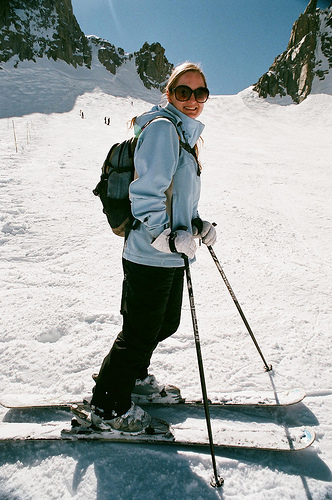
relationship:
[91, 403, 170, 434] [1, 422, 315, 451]
foot standing on ski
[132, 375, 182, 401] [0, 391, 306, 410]
foot standing on ski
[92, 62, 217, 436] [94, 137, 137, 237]
woman wearing backpack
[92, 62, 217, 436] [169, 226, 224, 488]
woman holding ski pole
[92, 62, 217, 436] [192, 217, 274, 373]
woman holding ski pole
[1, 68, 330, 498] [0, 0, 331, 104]
snow resting on mountains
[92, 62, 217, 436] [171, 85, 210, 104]
woman wearing shades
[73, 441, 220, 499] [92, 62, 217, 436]
shadow of woman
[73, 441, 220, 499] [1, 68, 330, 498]
shadow visible on snow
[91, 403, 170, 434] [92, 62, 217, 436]
foot of woman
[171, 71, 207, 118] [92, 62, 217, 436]
face of woman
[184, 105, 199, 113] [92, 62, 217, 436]
mouth of woman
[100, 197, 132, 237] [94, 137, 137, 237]
part of backpack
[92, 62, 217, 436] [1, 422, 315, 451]
woman standing on ski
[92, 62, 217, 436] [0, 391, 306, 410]
woman standing on ski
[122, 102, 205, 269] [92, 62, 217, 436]
jacket worn by woman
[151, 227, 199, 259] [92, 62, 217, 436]
glove worn by woman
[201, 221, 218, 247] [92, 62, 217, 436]
glove worn by woman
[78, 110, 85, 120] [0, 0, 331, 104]
skiers standing on mountains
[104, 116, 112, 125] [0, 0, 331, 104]
skiers standing on mountains